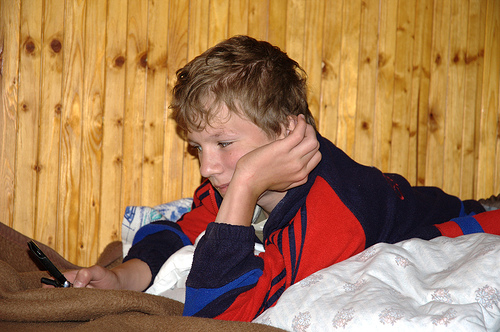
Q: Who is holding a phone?
A: The boy.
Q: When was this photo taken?
A: While in bed.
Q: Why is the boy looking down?
A: He is using a phone.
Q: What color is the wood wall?
A: Brown.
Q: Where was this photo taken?
A: In a bedroom.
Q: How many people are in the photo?
A: 1.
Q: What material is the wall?
A: Wood.